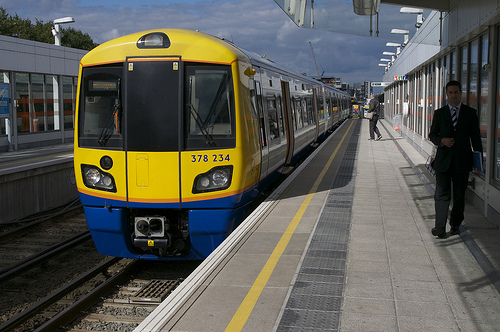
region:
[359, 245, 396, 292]
part of a floor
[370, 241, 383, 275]
part of a floor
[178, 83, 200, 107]
part of a window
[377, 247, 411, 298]
part of a floor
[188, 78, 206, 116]
part of a glass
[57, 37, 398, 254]
this is a train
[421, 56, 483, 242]
this is a person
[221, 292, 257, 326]
this is a yellow line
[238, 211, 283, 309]
this is a yellow line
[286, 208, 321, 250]
this is a yellow line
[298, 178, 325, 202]
this is a yellow line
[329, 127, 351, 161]
this is a yellow line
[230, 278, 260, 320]
this is a yellow line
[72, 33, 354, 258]
blue and yellow train at the station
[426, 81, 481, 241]
man in a business suit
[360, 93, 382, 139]
man walking to the train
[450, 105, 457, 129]
black and gray tie on the man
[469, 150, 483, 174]
blue notebook in the man's hand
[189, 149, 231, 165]
numbers 378 234 on the front of the train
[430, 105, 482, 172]
black suit coat on the man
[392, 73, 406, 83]
red, white, and blue sign on the building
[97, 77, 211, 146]
black windshield wiper blades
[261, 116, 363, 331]
gray metal grates on the ground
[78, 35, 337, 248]
a yellow and blue train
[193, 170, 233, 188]
the headlight on the train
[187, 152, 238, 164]
numbers on the front of the train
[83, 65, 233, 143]
the windshield on the train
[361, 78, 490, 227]
people standing on the train platform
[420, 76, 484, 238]
a man in a suit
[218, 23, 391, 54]
clouds behind the train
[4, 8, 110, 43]
trees behind the building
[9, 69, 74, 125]
windows on the building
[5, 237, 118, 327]
the train tracks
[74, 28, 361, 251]
This is a train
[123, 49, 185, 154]
Window of a train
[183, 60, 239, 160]
Window of a train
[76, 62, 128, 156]
Window of a train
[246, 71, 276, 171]
Window of a train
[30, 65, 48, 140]
Window of a train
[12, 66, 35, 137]
Window of a train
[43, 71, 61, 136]
Window of a train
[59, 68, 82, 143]
Window of a train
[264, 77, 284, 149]
Window of a train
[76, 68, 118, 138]
glass window on the yellow train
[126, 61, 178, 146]
glass window on the yellow train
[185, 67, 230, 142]
glass window on the yellow train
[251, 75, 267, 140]
glass window on the yellow train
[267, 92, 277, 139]
glass window on the yellow train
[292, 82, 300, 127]
glass window on the yellow train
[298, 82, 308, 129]
glass window on the yellow train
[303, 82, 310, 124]
glass window on the yellow train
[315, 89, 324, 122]
glass window on the yellow train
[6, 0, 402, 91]
The cloudy sky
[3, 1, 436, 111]
A cloudy sky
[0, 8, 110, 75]
The trees to the left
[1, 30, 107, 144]
The building to the left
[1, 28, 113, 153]
A building to the left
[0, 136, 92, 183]
The platform to the left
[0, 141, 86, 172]
A platform to the left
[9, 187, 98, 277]
The empty train tracks